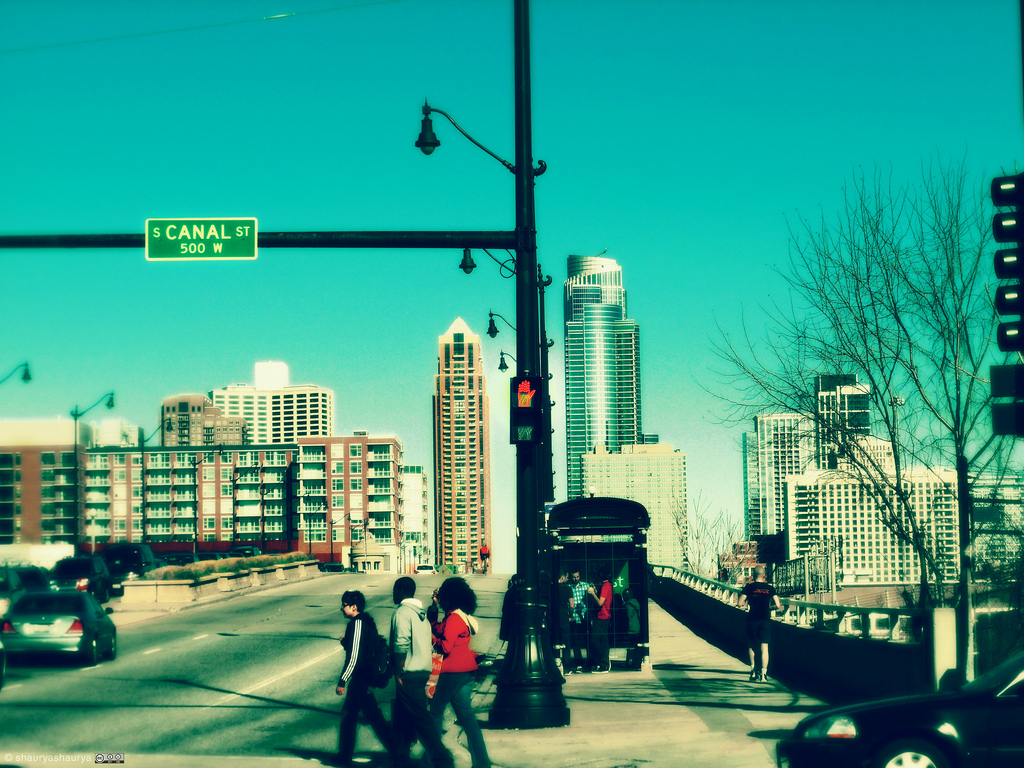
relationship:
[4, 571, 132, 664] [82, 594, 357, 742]
car on road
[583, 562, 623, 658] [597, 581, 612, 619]
man in red shirt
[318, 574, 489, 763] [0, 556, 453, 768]
people crossing roadside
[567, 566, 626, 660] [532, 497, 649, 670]
people standing under shelter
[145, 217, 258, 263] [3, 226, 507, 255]
sign on pole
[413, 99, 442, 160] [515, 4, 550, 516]
light hanging on pole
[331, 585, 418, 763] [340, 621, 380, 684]
woman has on black jacket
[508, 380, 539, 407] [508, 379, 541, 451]
red hand on sign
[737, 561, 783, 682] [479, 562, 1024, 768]
man walking on street corner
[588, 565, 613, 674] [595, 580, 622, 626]
man has on red shirt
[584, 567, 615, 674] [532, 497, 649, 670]
person at shelter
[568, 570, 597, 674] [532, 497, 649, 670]
person at shelter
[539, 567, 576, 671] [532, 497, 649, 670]
person at shelter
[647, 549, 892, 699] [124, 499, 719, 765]
railing on bridge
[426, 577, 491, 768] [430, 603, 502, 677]
people wearing coat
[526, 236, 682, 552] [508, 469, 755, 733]
building behind bus stop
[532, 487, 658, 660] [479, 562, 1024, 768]
shelter on street corner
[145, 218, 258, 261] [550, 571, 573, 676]
sign on person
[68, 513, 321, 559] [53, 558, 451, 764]
flowers growing alongside roadside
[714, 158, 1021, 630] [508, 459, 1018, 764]
bare tree at street corner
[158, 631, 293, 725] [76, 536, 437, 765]
lines painted in road